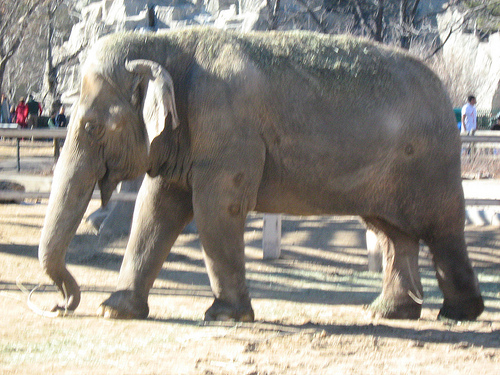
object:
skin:
[37, 28, 483, 324]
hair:
[90, 25, 405, 102]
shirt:
[458, 103, 477, 133]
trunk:
[35, 143, 105, 316]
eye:
[82, 120, 101, 138]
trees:
[0, 0, 47, 110]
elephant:
[36, 24, 487, 322]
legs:
[421, 227, 485, 323]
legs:
[357, 213, 424, 320]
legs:
[191, 172, 262, 322]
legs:
[97, 171, 195, 320]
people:
[54, 105, 69, 129]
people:
[458, 94, 479, 149]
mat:
[92, 26, 407, 112]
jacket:
[14, 105, 27, 124]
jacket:
[22, 100, 43, 118]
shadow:
[254, 319, 499, 349]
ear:
[114, 59, 181, 158]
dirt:
[0, 129, 498, 374]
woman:
[11, 96, 29, 130]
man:
[22, 94, 43, 130]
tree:
[446, 0, 498, 45]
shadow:
[0, 242, 379, 307]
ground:
[0, 129, 499, 374]